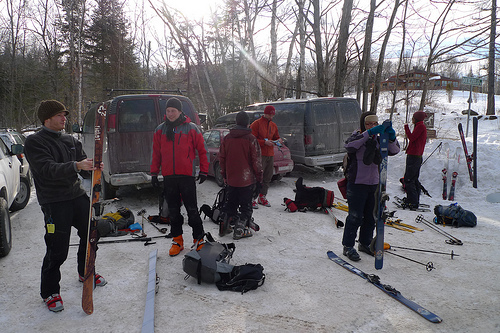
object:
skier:
[20, 96, 109, 319]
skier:
[145, 95, 214, 258]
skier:
[214, 107, 268, 245]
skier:
[338, 112, 408, 272]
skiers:
[391, 109, 431, 213]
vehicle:
[198, 110, 295, 187]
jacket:
[148, 116, 209, 178]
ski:
[79, 99, 111, 315]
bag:
[431, 201, 479, 228]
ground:
[443, 290, 499, 333]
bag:
[279, 172, 337, 214]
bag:
[215, 261, 269, 295]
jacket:
[341, 130, 404, 187]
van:
[241, 95, 370, 178]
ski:
[372, 120, 391, 271]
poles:
[384, 249, 425, 266]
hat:
[36, 98, 69, 124]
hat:
[162, 96, 182, 112]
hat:
[235, 110, 251, 127]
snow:
[256, 294, 357, 327]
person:
[248, 104, 284, 208]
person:
[215, 110, 265, 241]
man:
[143, 90, 216, 258]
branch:
[264, 0, 294, 36]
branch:
[433, 40, 488, 64]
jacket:
[216, 127, 265, 188]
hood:
[225, 125, 252, 138]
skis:
[455, 114, 484, 189]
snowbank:
[423, 137, 500, 205]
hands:
[370, 124, 386, 135]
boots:
[167, 234, 185, 258]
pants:
[162, 175, 207, 239]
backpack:
[181, 231, 238, 285]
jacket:
[21, 126, 93, 205]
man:
[20, 97, 114, 314]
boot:
[256, 193, 273, 207]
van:
[71, 88, 205, 202]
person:
[401, 109, 430, 212]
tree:
[77, 0, 149, 129]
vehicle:
[0, 127, 33, 256]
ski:
[322, 247, 448, 324]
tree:
[333, 0, 364, 97]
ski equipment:
[137, 247, 162, 333]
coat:
[146, 118, 211, 178]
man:
[335, 108, 405, 263]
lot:
[0, 92, 489, 318]